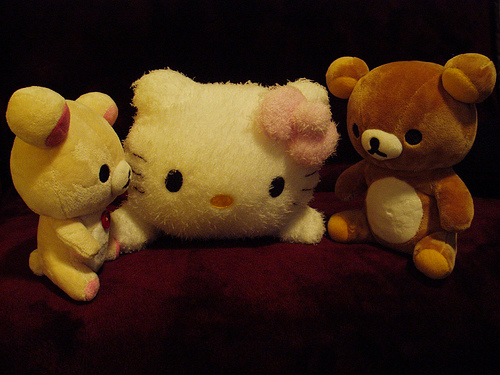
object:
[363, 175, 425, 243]
belly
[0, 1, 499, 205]
background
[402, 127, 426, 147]
eye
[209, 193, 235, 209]
nose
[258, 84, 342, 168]
bow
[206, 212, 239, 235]
mouth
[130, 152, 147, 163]
whiskers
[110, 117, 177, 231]
cheek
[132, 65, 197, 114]
ears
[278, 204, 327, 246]
feet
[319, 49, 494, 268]
animals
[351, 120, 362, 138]
eyes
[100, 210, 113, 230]
button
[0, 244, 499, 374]
chair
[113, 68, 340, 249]
cat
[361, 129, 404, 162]
nose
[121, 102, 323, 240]
head